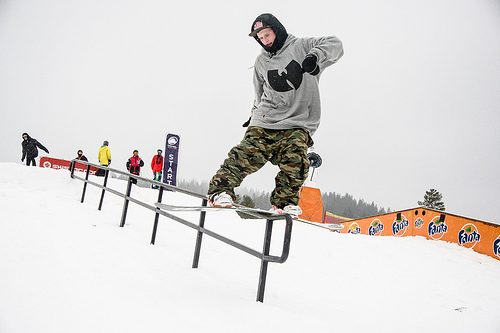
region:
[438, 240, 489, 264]
snow on a hill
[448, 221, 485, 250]
logo on a fence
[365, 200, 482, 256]
fence on a hill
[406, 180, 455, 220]
tree behind a fence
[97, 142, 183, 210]
people on a hill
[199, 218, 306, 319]
metal rail in the snow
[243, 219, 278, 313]
pole in the snow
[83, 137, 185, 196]
people behind the railing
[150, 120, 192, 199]
sign in the snow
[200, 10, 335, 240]
boy on the railing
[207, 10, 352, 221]
young man surf boarding on a metal rail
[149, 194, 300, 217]
surf board the man is using to surf the metal railing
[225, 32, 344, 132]
black and grey hoodie the surfboarder is wearing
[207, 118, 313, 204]
surfboarders camoflauge pants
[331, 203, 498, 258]
orange divider advertising Fanta Soda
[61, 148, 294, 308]
metal railing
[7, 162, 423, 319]
heavy snow coverage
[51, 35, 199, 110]
grey cloudy sky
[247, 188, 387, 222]
tree lined mountain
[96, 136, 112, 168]
person in yellow coat standing amongst 4 others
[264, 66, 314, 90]
The black WuTang Clan emblem on the guy's hoodie.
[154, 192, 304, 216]
The snowboard the guy is on.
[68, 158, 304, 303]
The railing the snowboarder is riding on.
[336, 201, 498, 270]
The orange Fanta sign.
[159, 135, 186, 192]
The purple Start sign.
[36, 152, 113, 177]
The red sign near the people.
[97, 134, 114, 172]
The person in the yellow jacket.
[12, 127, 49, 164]
The person dressed in all black on the left.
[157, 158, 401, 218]
The trees in the background.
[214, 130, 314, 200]
The fatigue pants the snowboarder is wearing.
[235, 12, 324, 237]
The man has camo pants.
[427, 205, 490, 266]
Sponsor logo on orange fence.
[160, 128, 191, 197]
Starting point for performance.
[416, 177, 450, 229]
Tree behind fence.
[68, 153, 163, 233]
Stair railing sticking out from snow.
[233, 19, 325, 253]
Man skateboarding on rail.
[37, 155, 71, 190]
Snow at the event.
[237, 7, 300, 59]
The man is wearing a covered hat.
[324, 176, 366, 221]
Tree line in the background.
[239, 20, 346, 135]
Man is wearing a gray sweatshirt.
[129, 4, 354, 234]
snowboarder riding the rail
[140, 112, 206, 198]
start sign at top of hill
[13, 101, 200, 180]
group of snowboarders waiting for their turn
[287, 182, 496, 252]
fanta advertisement along structure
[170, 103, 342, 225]
snowboarder wearing camoflauge pants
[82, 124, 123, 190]
person in yellow looking in opposite direction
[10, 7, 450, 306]
winter scene at ski resort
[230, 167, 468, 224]
evergreen trees in the distance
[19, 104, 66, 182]
snowboarder getting ready to descend the hill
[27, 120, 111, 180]
red sign at top of hill